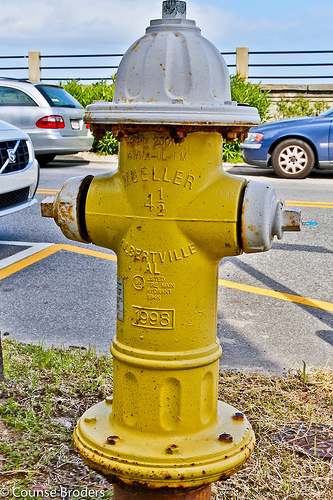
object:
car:
[238, 107, 332, 180]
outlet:
[236, 176, 302, 257]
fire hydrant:
[40, 0, 302, 499]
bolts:
[165, 444, 181, 453]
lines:
[217, 277, 333, 318]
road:
[0, 152, 332, 371]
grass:
[57, 68, 274, 163]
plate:
[71, 394, 256, 490]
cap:
[160, 1, 186, 25]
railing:
[0, 48, 332, 95]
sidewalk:
[57, 150, 273, 174]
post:
[234, 48, 249, 80]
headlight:
[243, 131, 262, 146]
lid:
[111, 19, 231, 107]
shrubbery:
[274, 95, 331, 124]